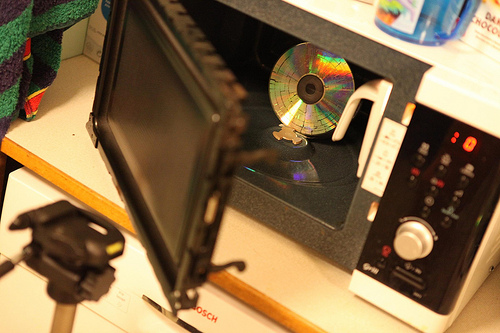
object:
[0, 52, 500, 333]
table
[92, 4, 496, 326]
microwave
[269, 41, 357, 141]
cd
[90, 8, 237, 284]
door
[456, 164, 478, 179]
button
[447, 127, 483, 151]
digit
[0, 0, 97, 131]
cloth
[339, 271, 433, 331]
edge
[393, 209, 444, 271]
switch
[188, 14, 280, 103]
space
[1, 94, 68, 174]
surface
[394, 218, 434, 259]
knob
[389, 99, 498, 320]
panel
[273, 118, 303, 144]
turntable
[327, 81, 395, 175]
handle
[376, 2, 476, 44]
container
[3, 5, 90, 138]
towel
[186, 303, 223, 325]
word